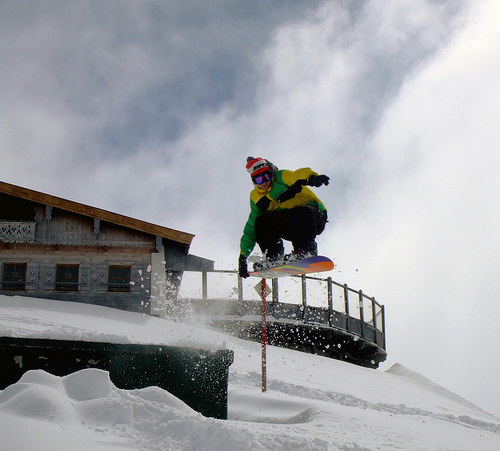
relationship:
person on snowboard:
[231, 152, 331, 264] [239, 251, 338, 278]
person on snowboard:
[236, 156, 330, 280] [247, 255, 335, 285]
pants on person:
[224, 196, 348, 253] [236, 156, 330, 280]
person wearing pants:
[236, 156, 330, 280] [224, 196, 348, 253]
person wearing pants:
[236, 156, 330, 280] [255, 207, 327, 261]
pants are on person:
[255, 207, 327, 261] [236, 156, 330, 280]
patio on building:
[168, 252, 393, 364] [3, 162, 415, 424]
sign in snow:
[238, 275, 282, 417] [4, 289, 499, 445]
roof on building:
[1, 176, 195, 249] [0, 177, 387, 368]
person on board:
[236, 156, 330, 280] [233, 243, 339, 285]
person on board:
[236, 156, 330, 280] [248, 255, 333, 278]